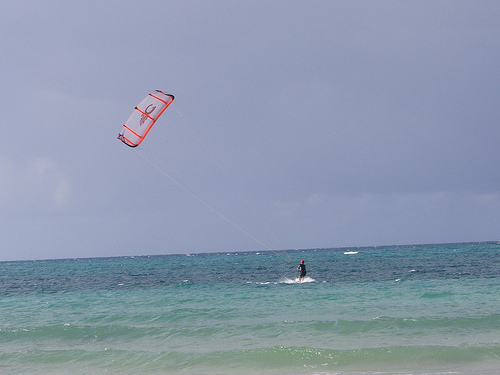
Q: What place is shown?
A: It is an ocean.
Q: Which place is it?
A: It is an ocean.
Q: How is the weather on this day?
A: It is clear.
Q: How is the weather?
A: It is clear.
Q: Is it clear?
A: Yes, it is clear.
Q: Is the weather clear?
A: Yes, it is clear.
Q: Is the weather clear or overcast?
A: It is clear.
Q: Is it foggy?
A: No, it is clear.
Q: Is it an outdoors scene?
A: Yes, it is outdoors.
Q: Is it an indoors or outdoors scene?
A: It is outdoors.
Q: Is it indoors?
A: No, it is outdoors.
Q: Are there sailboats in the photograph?
A: No, there are no sailboats.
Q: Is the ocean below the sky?
A: Yes, the ocean is below the sky.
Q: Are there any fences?
A: No, there are no fences.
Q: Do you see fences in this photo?
A: No, there are no fences.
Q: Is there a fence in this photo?
A: No, there are no fences.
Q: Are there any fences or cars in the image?
A: No, there are no fences or cars.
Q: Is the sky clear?
A: Yes, the sky is clear.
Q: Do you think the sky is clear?
A: Yes, the sky is clear.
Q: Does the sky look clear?
A: Yes, the sky is clear.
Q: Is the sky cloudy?
A: No, the sky is clear.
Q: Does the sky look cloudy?
A: No, the sky is clear.